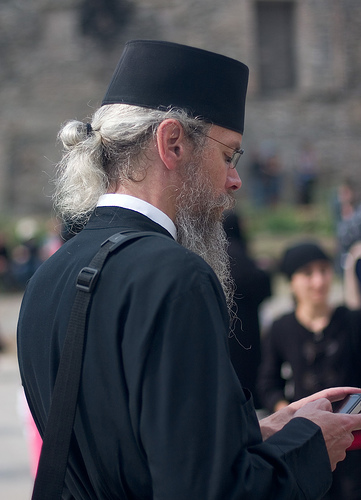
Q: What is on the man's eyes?
A: Eyeglasses.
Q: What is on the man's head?
A: A hat.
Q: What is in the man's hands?
A: A cell phone.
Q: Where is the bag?
A: Over the man's right shoulder.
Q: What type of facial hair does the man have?
A: A long beard.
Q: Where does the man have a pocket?
A: His right breast.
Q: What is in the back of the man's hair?
A: A hair tie.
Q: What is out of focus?
A: Everything except for the man.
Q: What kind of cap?
A: Flat.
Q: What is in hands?
A: Phone.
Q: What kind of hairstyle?
A: Ponytail.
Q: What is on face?
A: Beard.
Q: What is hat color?
A: Black.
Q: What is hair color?
A: Gray.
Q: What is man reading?
A: Cell phone.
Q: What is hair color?
A: Grey.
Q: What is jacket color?
A: Blue.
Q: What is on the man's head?
A: A hat.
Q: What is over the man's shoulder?
A: A strap.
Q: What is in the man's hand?
A: A phone.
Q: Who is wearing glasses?
A: The man.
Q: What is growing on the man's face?
A: A bears.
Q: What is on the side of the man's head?
A: His ear.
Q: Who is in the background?
A: A woman.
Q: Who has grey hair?
A: The man.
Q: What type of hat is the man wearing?
A: A fez.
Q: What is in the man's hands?
A: A phone.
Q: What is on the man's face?
A: Glasses.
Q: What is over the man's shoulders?
A: A strap.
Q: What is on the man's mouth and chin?
A: A beard.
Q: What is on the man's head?
A: A hat.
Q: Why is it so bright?
A: Sun light.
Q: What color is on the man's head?
A: A hat.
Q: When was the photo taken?
A: Day time.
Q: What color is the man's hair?
A: Gray.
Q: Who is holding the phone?
A: The man.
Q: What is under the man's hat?
A: Ponytail.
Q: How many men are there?
A: One.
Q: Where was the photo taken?
A: Near man.